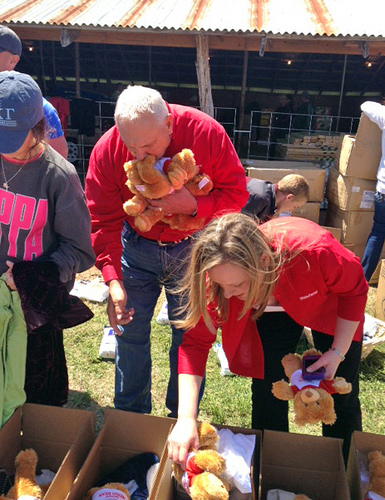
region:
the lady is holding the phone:
[300, 359, 327, 373]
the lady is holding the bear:
[320, 363, 338, 401]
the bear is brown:
[303, 394, 325, 419]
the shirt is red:
[295, 264, 324, 287]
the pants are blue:
[129, 287, 143, 311]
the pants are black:
[265, 336, 281, 356]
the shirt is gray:
[33, 166, 58, 189]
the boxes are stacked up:
[347, 158, 364, 241]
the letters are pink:
[10, 211, 36, 233]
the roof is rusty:
[182, 4, 208, 24]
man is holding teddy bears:
[108, 155, 204, 234]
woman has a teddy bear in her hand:
[281, 342, 348, 428]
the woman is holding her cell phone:
[302, 338, 319, 393]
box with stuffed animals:
[99, 417, 145, 494]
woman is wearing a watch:
[332, 340, 350, 359]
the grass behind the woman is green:
[365, 361, 384, 415]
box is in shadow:
[253, 427, 323, 493]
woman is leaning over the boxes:
[223, 259, 341, 416]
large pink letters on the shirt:
[4, 183, 73, 262]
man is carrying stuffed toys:
[63, 87, 236, 297]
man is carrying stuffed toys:
[73, 80, 229, 241]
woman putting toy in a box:
[147, 189, 286, 497]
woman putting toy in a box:
[154, 206, 259, 497]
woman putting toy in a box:
[163, 205, 257, 480]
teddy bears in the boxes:
[17, 418, 277, 497]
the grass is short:
[222, 394, 243, 407]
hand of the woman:
[161, 418, 205, 447]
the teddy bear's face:
[289, 388, 336, 414]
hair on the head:
[111, 91, 156, 119]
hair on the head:
[205, 227, 254, 258]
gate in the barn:
[242, 98, 324, 143]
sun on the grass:
[81, 368, 104, 383]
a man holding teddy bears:
[86, 83, 249, 417]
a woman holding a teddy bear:
[159, 206, 369, 469]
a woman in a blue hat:
[0, 70, 96, 406]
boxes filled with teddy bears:
[0, 400, 383, 499]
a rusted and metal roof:
[0, 0, 384, 40]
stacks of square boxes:
[325, 111, 384, 284]